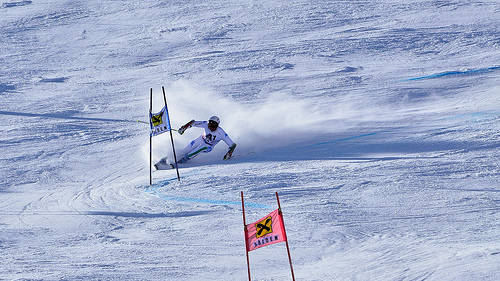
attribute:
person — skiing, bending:
[154, 114, 237, 171]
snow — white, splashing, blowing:
[1, 1, 500, 280]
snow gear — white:
[169, 121, 236, 161]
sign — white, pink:
[149, 85, 179, 188]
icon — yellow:
[152, 113, 164, 128]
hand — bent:
[223, 149, 233, 157]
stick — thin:
[149, 88, 152, 185]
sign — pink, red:
[241, 192, 296, 281]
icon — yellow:
[254, 217, 273, 238]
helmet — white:
[209, 114, 222, 123]